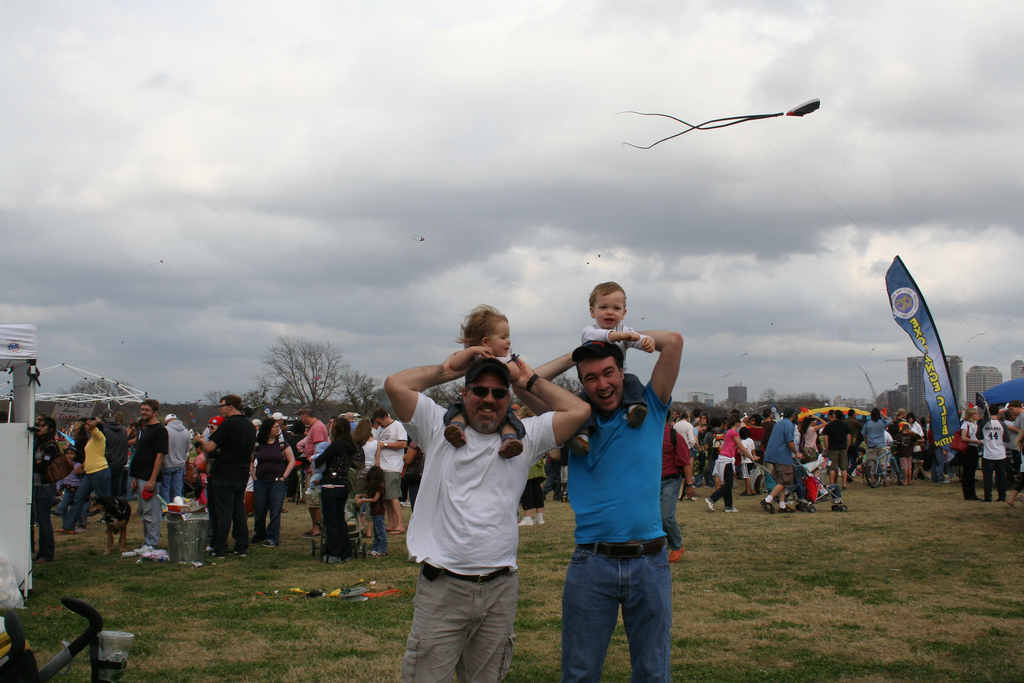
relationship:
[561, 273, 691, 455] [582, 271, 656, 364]
person looking at toddler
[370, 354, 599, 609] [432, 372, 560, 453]
man wearing sunglasses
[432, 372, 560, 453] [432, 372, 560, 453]
sunglasses on face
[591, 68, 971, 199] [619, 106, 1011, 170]
kite in sky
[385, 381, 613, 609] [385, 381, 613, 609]
man wearing shirt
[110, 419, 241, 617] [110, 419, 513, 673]
man standing on grass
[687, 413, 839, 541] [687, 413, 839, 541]
woman wearing pants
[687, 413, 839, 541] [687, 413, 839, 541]
woman wearing shirt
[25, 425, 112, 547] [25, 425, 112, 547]
woman carrying bag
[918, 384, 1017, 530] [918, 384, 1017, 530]
woman carrying bag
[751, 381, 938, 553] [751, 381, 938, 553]
man pushing baby carriage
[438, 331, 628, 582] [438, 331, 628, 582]
head of person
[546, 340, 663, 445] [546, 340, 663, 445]
head of person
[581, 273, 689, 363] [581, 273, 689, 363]
head of person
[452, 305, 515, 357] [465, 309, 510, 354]
head of person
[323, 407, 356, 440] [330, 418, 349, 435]
head of person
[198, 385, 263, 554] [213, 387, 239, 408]
head of person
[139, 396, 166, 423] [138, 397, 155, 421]
head of person